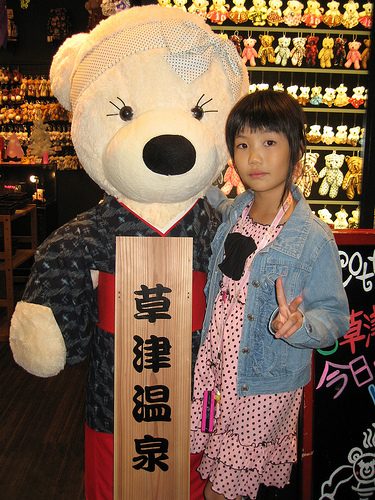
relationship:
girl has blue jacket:
[190, 90, 350, 498] [204, 188, 350, 393]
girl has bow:
[190, 90, 350, 498] [216, 228, 261, 283]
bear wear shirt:
[39, 28, 211, 380] [51, 198, 254, 397]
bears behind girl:
[44, 34, 279, 341] [188, 103, 333, 395]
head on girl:
[225, 90, 305, 191] [190, 90, 350, 498]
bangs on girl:
[235, 96, 287, 135] [190, 90, 350, 498]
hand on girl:
[247, 278, 317, 346] [108, 70, 362, 404]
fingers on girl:
[268, 277, 304, 316] [190, 90, 350, 498]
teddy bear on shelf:
[320, 150, 347, 200] [5, 242, 38, 271]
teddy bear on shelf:
[301, 0, 324, 30] [203, 24, 371, 38]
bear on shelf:
[206, 0, 228, 24] [209, 24, 370, 36]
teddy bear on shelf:
[333, 81, 352, 106] [232, 1, 373, 228]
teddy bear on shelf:
[319, 37, 334, 67] [142, 0, 370, 230]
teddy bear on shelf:
[346, 38, 360, 69] [142, 0, 370, 230]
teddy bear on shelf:
[272, 34, 291, 64] [142, 0, 370, 230]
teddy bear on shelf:
[320, 150, 344, 201] [142, 0, 370, 230]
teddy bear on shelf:
[340, 152, 360, 197] [142, 0, 370, 230]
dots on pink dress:
[261, 225, 265, 229] [186, 198, 305, 498]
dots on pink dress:
[230, 287, 234, 290] [186, 198, 305, 498]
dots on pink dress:
[245, 232, 248, 234] [186, 198, 305, 498]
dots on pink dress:
[223, 322, 228, 326] [186, 198, 305, 498]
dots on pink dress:
[209, 327, 214, 332] [186, 198, 305, 498]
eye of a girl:
[235, 141, 250, 152] [190, 90, 350, 498]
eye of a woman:
[263, 137, 276, 148] [188, 84, 350, 499]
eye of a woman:
[234, 139, 248, 149] [188, 84, 350, 499]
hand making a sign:
[267, 278, 303, 340] [265, 275, 314, 367]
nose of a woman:
[247, 148, 265, 164] [195, 85, 351, 340]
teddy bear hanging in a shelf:
[314, 150, 345, 205] [320, 140, 355, 213]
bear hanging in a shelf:
[318, 37, 339, 69] [281, 28, 366, 78]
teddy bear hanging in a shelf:
[345, 41, 360, 66] [322, 33, 356, 54]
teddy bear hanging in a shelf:
[317, 38, 333, 66] [322, 33, 356, 54]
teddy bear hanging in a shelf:
[240, 38, 258, 64] [322, 33, 356, 54]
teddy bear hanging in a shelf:
[302, 36, 320, 65] [212, 19, 373, 50]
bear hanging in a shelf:
[8, 3, 251, 498] [332, 149, 359, 187]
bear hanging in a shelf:
[257, 33, 276, 67] [275, 32, 345, 56]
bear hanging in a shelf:
[276, 28, 290, 72] [275, 32, 345, 56]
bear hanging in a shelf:
[321, 30, 335, 70] [275, 32, 345, 56]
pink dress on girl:
[193, 213, 313, 492] [190, 90, 350, 498]